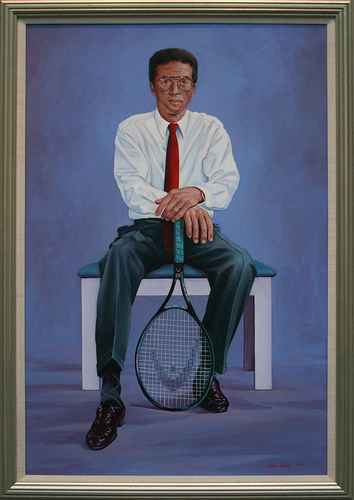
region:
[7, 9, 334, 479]
oil painting of man with tennis racket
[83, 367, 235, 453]
dress shoes on man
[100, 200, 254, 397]
green slacks on man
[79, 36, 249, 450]
man leaning on tennis racket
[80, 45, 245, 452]
man wearing white button up shirt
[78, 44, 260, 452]
man wearing a red tie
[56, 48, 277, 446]
man sitting on bench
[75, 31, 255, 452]
man with hands crossed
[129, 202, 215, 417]
tennis racket standing on head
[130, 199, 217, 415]
green tennis racket with green tape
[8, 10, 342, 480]
painting in a frame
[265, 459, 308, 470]
artist's signature in the bottom corner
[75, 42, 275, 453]
man sitting down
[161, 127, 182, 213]
red tie hanging down the torso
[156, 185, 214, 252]
hands resting on the handle of a tennis racket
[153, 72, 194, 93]
large glasses on the face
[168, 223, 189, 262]
blue handle on the racket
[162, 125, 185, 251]
deep red tie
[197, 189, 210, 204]
watch poking out from under the shirt sleeve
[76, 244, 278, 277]
blue cushion on the chair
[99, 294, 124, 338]
a man is wearing green pants.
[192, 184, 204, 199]
a man is wearing a watch.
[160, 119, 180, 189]
a man is wearing a burgundy tie.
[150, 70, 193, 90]
a man is wearing eye glasses.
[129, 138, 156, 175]
a man is wearing a white shirt.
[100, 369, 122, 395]
a man is wearing a pair of socks.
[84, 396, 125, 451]
a man is wearing a pair of burgundy shoes.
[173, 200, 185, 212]
a man is wearing a gold ring.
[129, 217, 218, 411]
a man is holding a tennis racket.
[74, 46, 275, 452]
a man sitting in a chair holdnig a tennis racket.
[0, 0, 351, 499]
Portrait of a man.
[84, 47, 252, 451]
man sitting on a bench.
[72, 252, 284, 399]
White bench under the man.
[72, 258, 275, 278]
cushion on the bench.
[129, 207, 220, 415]
Tennis racquet in the forefront.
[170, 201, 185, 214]
Ring on the finger.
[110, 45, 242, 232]
white shirt on the man.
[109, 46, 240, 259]
Red tie on the man.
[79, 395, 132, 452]
Dark brown shoe on the foot.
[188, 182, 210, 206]
Watch on the wrist.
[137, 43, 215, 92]
man has dark hair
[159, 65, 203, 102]
man is wearing glasses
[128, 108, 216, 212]
man has white shirt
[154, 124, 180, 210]
man has red tie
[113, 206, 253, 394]
man has blue pants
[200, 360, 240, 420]
man has dark red shoes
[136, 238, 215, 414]
man holds blue racket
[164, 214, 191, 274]
blue handle on racket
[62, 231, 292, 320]
man sits on blue cushion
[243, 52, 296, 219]
blue background behind man